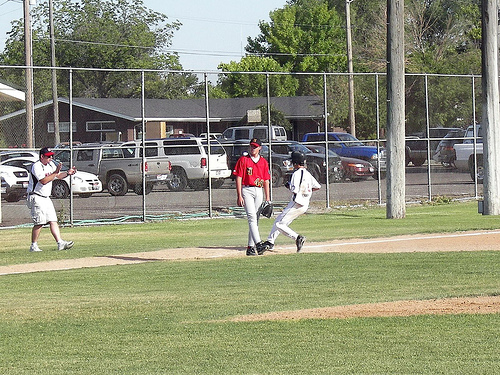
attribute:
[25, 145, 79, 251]
man — here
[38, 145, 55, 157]
cap — here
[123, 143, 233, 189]
car — white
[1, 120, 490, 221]
parking lot — parked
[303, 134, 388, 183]
truck — blue, parked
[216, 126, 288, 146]
van — silver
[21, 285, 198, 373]
grass — green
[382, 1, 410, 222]
pole — wooden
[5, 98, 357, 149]
building — here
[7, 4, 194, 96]
tree — here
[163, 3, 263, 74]
sky — here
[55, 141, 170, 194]
truck — grey, here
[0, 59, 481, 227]
fence — metal, chain link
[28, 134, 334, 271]
match — practice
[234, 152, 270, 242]
uniform — RED AND WHITE, for BASEBALL